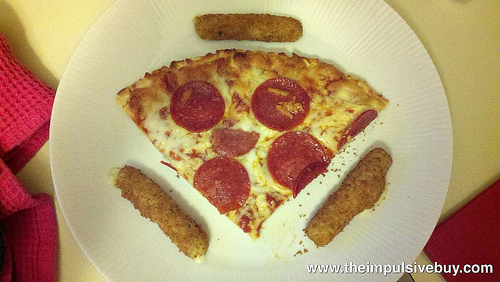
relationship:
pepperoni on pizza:
[167, 79, 226, 133] [101, 47, 394, 229]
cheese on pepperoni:
[315, 75, 360, 112] [248, 70, 313, 130]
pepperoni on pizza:
[208, 125, 261, 158] [116, 48, 388, 238]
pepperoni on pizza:
[337, 109, 377, 150] [101, 47, 394, 229]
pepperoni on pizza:
[247, 75, 317, 133] [109, 56, 359, 244]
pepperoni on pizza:
[247, 75, 317, 133] [114, 47, 389, 237]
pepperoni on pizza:
[298, 162, 326, 195] [103, 47, 370, 198]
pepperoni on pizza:
[172, 79, 223, 129] [101, 47, 394, 229]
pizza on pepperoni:
[114, 47, 389, 237] [191, 155, 253, 215]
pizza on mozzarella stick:
[114, 47, 389, 237] [292, 145, 402, 260]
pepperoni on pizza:
[172, 79, 222, 133] [115, 42, 368, 237]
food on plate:
[120, 49, 387, 232] [51, 0, 460, 280]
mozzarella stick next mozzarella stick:
[301, 146, 392, 247] [114, 163, 211, 261]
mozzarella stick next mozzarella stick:
[114, 163, 211, 261] [193, 11, 304, 45]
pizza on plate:
[114, 47, 389, 237] [51, 0, 460, 280]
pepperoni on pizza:
[178, 79, 258, 205] [144, 57, 372, 193]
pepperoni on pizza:
[262, 128, 333, 197] [114, 47, 389, 237]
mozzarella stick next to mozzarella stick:
[114, 163, 211, 261] [301, 146, 392, 247]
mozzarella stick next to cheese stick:
[114, 163, 211, 261] [189, 11, 302, 44]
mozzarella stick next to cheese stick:
[301, 146, 392, 247] [189, 11, 302, 44]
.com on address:
[456, 255, 498, 274] [286, 241, 466, 275]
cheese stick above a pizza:
[189, 11, 302, 44] [114, 47, 389, 237]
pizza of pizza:
[114, 47, 389, 237] [101, 47, 394, 229]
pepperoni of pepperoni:
[208, 125, 261, 158] [262, 128, 333, 197]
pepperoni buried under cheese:
[262, 128, 333, 197] [120, 55, 380, 239]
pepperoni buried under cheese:
[208, 125, 261, 158] [120, 55, 380, 239]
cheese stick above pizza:
[189, 11, 299, 44] [102, 40, 307, 176]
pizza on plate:
[102, 40, 307, 176] [51, 0, 460, 280]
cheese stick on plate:
[189, 11, 299, 44] [51, 0, 460, 280]